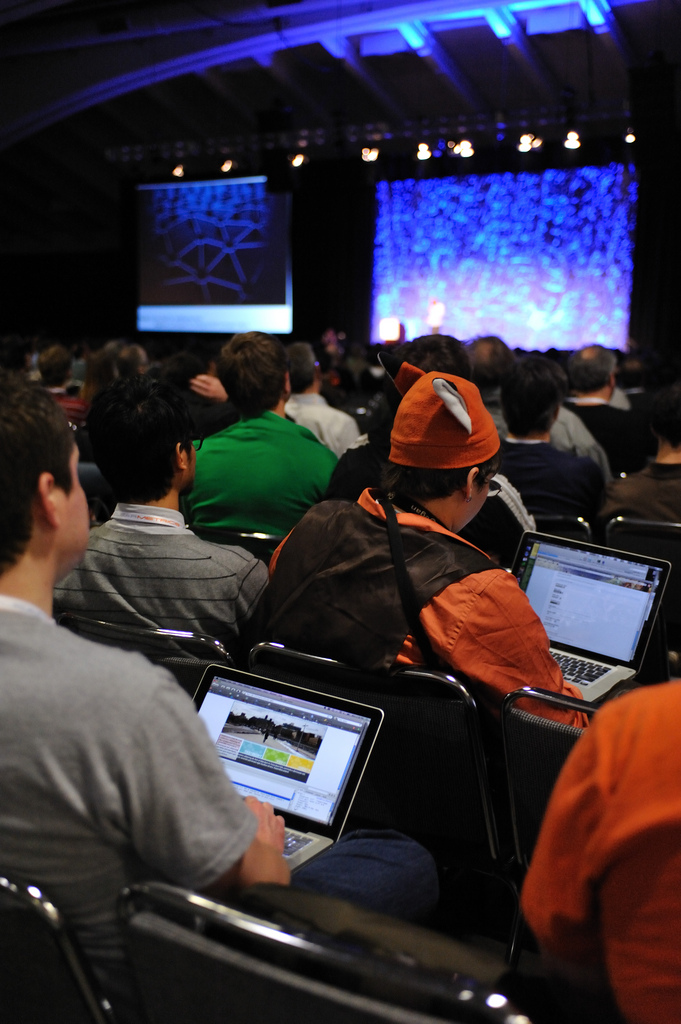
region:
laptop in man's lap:
[160, 655, 390, 885]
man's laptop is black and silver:
[137, 651, 384, 887]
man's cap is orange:
[375, 354, 501, 470]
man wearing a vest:
[238, 482, 508, 671]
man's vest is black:
[252, 484, 506, 681]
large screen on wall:
[126, 174, 305, 343]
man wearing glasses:
[177, 424, 212, 456]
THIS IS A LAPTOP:
[171, 639, 377, 898]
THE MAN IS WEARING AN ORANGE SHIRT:
[516, 673, 677, 1008]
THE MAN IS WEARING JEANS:
[272, 817, 454, 951]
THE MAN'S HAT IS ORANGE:
[370, 350, 501, 479]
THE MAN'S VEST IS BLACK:
[231, 488, 516, 700]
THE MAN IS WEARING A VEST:
[250, 489, 508, 703]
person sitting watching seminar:
[253, 359, 583, 728]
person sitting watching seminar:
[0, 371, 293, 989]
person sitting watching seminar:
[62, 374, 262, 647]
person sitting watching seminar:
[177, 328, 340, 533]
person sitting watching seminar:
[483, 348, 602, 516]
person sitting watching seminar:
[566, 344, 651, 475]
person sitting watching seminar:
[464, 330, 518, 444]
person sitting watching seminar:
[285, 336, 367, 449]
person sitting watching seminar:
[113, 341, 155, 377]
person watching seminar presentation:
[262, 367, 586, 719]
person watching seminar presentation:
[63, 358, 267, 647]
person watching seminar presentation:
[191, 324, 333, 532]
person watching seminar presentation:
[284, 335, 364, 457]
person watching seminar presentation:
[488, 347, 597, 525]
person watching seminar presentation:
[597, 373, 677, 515]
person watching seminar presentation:
[459, 324, 511, 420]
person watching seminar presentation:
[31, 340, 89, 420]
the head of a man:
[350, 374, 504, 523]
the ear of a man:
[455, 454, 495, 514]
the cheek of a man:
[449, 477, 501, 531]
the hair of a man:
[388, 464, 443, 502]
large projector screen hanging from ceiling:
[135, 176, 302, 337]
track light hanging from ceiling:
[172, 162, 186, 182]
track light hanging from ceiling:
[222, 160, 232, 177]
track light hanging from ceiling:
[290, 153, 307, 167]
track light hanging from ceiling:
[361, 146, 382, 162]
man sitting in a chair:
[4, 380, 439, 994]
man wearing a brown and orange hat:
[257, 360, 586, 732]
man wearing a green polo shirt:
[186, 330, 346, 532]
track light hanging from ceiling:
[562, 130, 581, 152]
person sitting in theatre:
[244, 361, 584, 731]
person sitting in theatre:
[517, 678, 678, 1022]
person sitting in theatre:
[1, 362, 444, 1019]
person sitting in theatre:
[51, 376, 272, 656]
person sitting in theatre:
[592, 374, 677, 543]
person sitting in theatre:
[487, 355, 609, 537]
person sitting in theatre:
[184, 329, 341, 546]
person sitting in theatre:
[34, 341, 70, 401]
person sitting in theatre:
[277, 337, 356, 459]